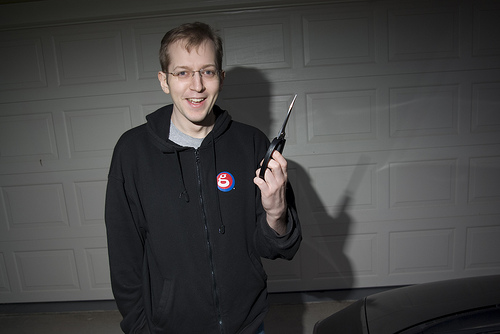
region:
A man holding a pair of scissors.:
[101, 18, 304, 330]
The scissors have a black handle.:
[255, 130, 290, 175]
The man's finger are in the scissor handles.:
[255, 135, 285, 180]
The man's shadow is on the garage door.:
[205, 65, 352, 300]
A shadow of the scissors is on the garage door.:
[330, 142, 380, 222]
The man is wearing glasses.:
[160, 65, 220, 80]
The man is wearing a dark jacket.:
[105, 111, 300, 331]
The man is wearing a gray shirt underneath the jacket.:
[165, 121, 201, 146]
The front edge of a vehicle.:
[305, 270, 490, 325]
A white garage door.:
[40, 20, 476, 295]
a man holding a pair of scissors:
[112, 25, 338, 276]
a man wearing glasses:
[136, 34, 258, 86]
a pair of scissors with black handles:
[244, 82, 307, 195]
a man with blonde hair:
[155, 23, 260, 86]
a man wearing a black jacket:
[95, 33, 244, 234]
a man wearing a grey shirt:
[156, 29, 251, 159]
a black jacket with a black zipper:
[179, 139, 234, 304]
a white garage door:
[281, 23, 460, 295]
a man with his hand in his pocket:
[103, 14, 244, 324]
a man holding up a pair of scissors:
[140, 30, 347, 218]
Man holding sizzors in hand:
[47, 15, 332, 330]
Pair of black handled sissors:
[245, 81, 305, 198]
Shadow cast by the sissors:
[320, 139, 400, 291]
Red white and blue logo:
[201, 165, 251, 215]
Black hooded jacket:
[90, 99, 291, 331]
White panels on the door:
[296, 90, 498, 213]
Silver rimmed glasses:
[156, 59, 239, 87]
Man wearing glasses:
[137, 28, 250, 116]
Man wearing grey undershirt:
[166, 118, 223, 165]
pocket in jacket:
[143, 266, 193, 326]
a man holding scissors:
[75, 17, 307, 328]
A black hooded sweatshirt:
[108, 99, 298, 331]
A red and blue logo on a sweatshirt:
[213, 166, 235, 198]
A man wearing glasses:
[153, 27, 224, 120]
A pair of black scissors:
[253, 83, 303, 195]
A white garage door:
[9, 20, 499, 273]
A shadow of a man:
[215, 49, 377, 331]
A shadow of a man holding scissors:
[217, 60, 377, 323]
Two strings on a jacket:
[170, 138, 230, 241]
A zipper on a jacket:
[188, 144, 223, 333]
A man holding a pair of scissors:
[102, 21, 299, 332]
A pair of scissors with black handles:
[260, 91, 297, 178]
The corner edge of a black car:
[313, 276, 498, 332]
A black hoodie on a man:
[102, 103, 303, 332]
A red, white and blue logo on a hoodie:
[215, 169, 235, 192]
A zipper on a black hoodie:
[190, 146, 224, 332]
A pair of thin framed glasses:
[160, 68, 227, 81]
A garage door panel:
[302, 89, 379, 142]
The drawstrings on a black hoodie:
[173, 134, 227, 236]